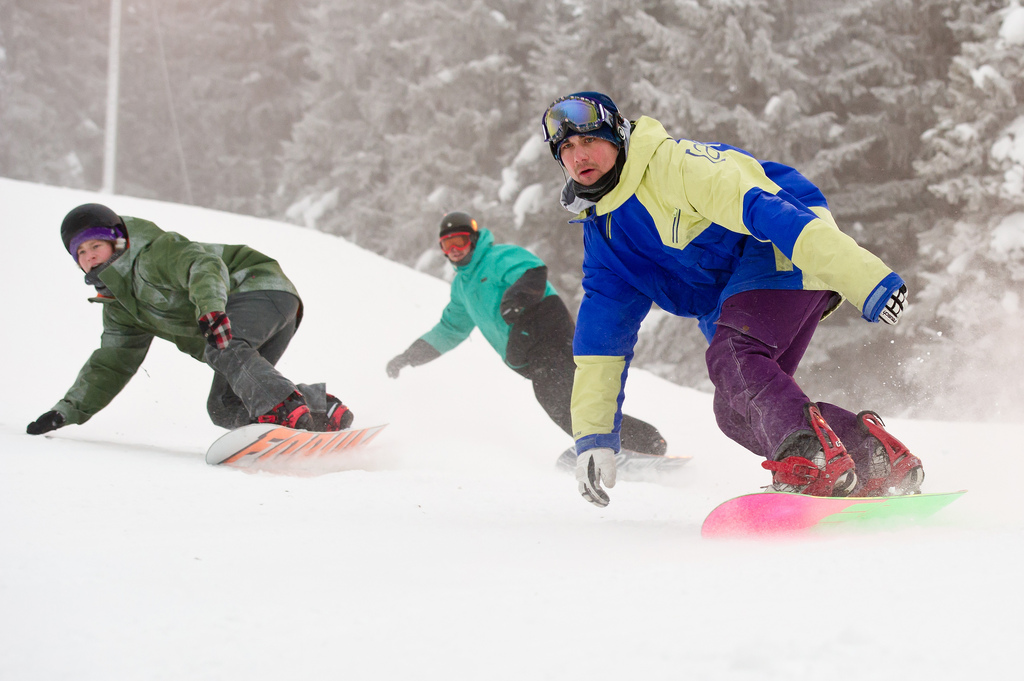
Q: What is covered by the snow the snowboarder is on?
A: The ground is covered by the snow.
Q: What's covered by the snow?
A: The ground is covered by the snow.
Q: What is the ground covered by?
A: The ground is covered by the snow.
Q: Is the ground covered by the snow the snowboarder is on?
A: Yes, the ground is covered by the snow.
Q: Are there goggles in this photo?
A: Yes, there are goggles.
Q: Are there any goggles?
A: Yes, there are goggles.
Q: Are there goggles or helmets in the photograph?
A: Yes, there are goggles.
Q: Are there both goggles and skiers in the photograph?
A: Yes, there are both goggles and a skier.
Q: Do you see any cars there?
A: No, there are no cars.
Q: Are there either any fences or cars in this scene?
A: No, there are no cars or fences.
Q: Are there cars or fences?
A: No, there are no cars or fences.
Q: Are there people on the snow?
A: Yes, there is a person on the snow.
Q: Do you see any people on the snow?
A: Yes, there is a person on the snow.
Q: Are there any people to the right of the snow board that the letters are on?
A: Yes, there is a person to the right of the snowboard.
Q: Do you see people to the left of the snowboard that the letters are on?
A: No, the person is to the right of the snow board.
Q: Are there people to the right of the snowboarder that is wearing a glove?
A: Yes, there is a person to the right of the snowboarder.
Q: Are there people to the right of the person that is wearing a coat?
A: Yes, there is a person to the right of the snowboarder.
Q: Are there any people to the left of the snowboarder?
A: No, the person is to the right of the snowboarder.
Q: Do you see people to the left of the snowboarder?
A: No, the person is to the right of the snowboarder.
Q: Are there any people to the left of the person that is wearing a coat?
A: No, the person is to the right of the snowboarder.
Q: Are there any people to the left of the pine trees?
A: Yes, there is a person to the left of the pine trees.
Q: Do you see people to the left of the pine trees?
A: Yes, there is a person to the left of the pine trees.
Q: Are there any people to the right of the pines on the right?
A: No, the person is to the left of the pines.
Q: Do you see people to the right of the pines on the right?
A: No, the person is to the left of the pines.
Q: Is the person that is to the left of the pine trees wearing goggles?
A: Yes, the person is wearing goggles.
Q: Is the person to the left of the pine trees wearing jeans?
A: No, the person is wearing goggles.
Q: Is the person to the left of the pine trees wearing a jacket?
A: Yes, the person is wearing a jacket.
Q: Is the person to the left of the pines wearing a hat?
A: No, the person is wearing a jacket.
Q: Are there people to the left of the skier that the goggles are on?
A: Yes, there is a person to the left of the skier.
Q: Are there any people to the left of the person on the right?
A: Yes, there is a person to the left of the skier.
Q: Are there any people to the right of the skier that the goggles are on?
A: No, the person is to the left of the skier.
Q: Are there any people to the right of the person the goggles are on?
A: No, the person is to the left of the skier.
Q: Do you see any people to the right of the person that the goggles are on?
A: No, the person is to the left of the skier.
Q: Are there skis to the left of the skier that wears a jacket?
A: No, there is a person to the left of the skier.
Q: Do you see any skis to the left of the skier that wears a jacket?
A: No, there is a person to the left of the skier.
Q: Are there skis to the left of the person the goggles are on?
A: No, there is a person to the left of the skier.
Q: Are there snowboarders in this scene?
A: Yes, there is a snowboarder.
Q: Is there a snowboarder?
A: Yes, there is a snowboarder.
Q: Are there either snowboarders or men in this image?
A: Yes, there is a snowboarder.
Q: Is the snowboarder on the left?
A: Yes, the snowboarder is on the left of the image.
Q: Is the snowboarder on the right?
A: No, the snowboarder is on the left of the image.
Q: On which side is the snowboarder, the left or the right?
A: The snowboarder is on the left of the image.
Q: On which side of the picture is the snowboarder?
A: The snowboarder is on the left of the image.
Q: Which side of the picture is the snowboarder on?
A: The snowboarder is on the left of the image.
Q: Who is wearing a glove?
A: The snowboarder is wearing a glove.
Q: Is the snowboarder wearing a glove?
A: Yes, the snowboarder is wearing a glove.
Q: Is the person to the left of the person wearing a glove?
A: Yes, the snowboarder is wearing a glove.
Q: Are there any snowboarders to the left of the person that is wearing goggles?
A: Yes, there is a snowboarder to the left of the person.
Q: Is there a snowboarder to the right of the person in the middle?
A: No, the snowboarder is to the left of the person.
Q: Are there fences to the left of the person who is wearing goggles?
A: No, there is a snowboarder to the left of the person.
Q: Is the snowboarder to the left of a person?
A: Yes, the snowboarder is to the left of a person.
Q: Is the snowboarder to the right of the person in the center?
A: No, the snowboarder is to the left of the person.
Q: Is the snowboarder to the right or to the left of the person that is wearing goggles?
A: The snowboarder is to the left of the person.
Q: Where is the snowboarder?
A: The snowboarder is on the snow.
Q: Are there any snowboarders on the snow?
A: Yes, there is a snowboarder on the snow.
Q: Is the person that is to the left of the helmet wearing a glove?
A: Yes, the snowboarder is wearing a glove.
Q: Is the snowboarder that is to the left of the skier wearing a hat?
A: No, the snowboarder is wearing a glove.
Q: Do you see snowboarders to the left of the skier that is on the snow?
A: Yes, there is a snowboarder to the left of the skier.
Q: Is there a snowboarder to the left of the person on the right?
A: Yes, there is a snowboarder to the left of the skier.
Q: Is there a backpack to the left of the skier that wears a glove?
A: No, there is a snowboarder to the left of the skier.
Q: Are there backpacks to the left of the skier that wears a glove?
A: No, there is a snowboarder to the left of the skier.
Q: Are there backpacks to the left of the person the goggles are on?
A: No, there is a snowboarder to the left of the skier.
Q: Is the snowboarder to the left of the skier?
A: Yes, the snowboarder is to the left of the skier.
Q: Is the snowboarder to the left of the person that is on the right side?
A: Yes, the snowboarder is to the left of the skier.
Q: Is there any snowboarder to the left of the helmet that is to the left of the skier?
A: Yes, there is a snowboarder to the left of the helmet.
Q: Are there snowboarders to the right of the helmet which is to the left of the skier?
A: No, the snowboarder is to the left of the helmet.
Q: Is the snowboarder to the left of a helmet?
A: Yes, the snowboarder is to the left of a helmet.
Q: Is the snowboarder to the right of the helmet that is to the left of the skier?
A: No, the snowboarder is to the left of the helmet.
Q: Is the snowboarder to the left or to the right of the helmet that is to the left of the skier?
A: The snowboarder is to the left of the helmet.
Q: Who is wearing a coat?
A: The snowboarder is wearing a coat.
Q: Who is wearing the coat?
A: The snowboarder is wearing a coat.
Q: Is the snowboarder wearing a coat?
A: Yes, the snowboarder is wearing a coat.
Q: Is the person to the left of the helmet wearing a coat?
A: Yes, the snowboarder is wearing a coat.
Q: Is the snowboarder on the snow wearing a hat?
A: No, the snowboarder is wearing a coat.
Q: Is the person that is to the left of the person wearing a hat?
A: No, the snowboarder is wearing a coat.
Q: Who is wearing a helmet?
A: The snowboarder is wearing a helmet.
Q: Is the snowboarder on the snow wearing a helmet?
A: Yes, the snowboarder is wearing a helmet.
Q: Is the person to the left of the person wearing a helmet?
A: Yes, the snowboarder is wearing a helmet.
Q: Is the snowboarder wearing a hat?
A: No, the snowboarder is wearing a helmet.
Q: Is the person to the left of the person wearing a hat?
A: No, the snowboarder is wearing a helmet.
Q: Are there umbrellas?
A: No, there are no umbrellas.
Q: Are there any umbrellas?
A: No, there are no umbrellas.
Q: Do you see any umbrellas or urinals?
A: No, there are no umbrellas or urinals.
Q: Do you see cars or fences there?
A: No, there are no fences or cars.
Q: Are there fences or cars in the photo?
A: No, there are no fences or cars.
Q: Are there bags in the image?
A: No, there are no bags.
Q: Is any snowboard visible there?
A: Yes, there is a snowboard.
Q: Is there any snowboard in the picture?
A: Yes, there is a snowboard.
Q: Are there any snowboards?
A: Yes, there is a snowboard.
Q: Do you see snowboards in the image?
A: Yes, there is a snowboard.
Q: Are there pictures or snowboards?
A: Yes, there is a snowboard.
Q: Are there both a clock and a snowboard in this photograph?
A: No, there is a snowboard but no clocks.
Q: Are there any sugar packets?
A: No, there are no sugar packets.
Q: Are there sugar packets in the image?
A: No, there are no sugar packets.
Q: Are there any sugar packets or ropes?
A: No, there are no sugar packets or ropes.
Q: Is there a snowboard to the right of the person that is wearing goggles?
A: Yes, there is a snowboard to the right of the person.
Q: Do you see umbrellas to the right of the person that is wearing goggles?
A: No, there is a snowboard to the right of the person.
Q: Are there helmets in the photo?
A: Yes, there is a helmet.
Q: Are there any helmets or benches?
A: Yes, there is a helmet.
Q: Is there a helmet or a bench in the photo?
A: Yes, there is a helmet.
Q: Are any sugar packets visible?
A: No, there are no sugar packets.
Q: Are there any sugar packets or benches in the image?
A: No, there are no sugar packets or benches.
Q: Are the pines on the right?
A: Yes, the pines are on the right of the image.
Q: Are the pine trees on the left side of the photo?
A: No, the pine trees are on the right of the image.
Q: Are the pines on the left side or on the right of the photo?
A: The pines are on the right of the image.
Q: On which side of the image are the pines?
A: The pines are on the right of the image.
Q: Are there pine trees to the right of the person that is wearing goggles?
A: Yes, there are pine trees to the right of the person.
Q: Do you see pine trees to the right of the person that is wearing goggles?
A: Yes, there are pine trees to the right of the person.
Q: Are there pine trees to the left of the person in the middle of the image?
A: No, the pine trees are to the right of the person.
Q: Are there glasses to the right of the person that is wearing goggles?
A: No, there are pine trees to the right of the person.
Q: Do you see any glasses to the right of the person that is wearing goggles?
A: No, there are pine trees to the right of the person.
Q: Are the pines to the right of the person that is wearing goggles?
A: Yes, the pines are to the right of the person.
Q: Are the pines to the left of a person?
A: No, the pines are to the right of a person.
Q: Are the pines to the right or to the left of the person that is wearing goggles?
A: The pines are to the right of the person.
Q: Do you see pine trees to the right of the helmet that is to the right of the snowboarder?
A: Yes, there are pine trees to the right of the helmet.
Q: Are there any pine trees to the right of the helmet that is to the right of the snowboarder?
A: Yes, there are pine trees to the right of the helmet.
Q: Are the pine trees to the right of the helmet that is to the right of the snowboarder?
A: Yes, the pine trees are to the right of the helmet.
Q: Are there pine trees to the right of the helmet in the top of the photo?
A: Yes, there are pine trees to the right of the helmet.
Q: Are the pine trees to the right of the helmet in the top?
A: Yes, the pine trees are to the right of the helmet.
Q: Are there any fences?
A: No, there are no fences.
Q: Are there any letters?
A: Yes, there are letters.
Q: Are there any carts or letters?
A: Yes, there are letters.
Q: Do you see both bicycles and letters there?
A: No, there are letters but no bikes.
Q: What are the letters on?
A: The letters are on the snowboard.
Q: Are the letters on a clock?
A: No, the letters are on the snowboard.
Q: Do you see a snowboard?
A: Yes, there is a snowboard.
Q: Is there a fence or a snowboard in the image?
A: Yes, there is a snowboard.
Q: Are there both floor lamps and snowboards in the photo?
A: No, there is a snowboard but no floor lamps.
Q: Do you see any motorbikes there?
A: No, there are no motorbikes.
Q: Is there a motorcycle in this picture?
A: No, there are no motorcycles.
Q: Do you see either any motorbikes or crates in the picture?
A: No, there are no motorbikes or crates.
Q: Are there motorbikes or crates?
A: No, there are no motorbikes or crates.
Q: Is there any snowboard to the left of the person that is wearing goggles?
A: Yes, there is a snowboard to the left of the person.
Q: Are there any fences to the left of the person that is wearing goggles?
A: No, there is a snowboard to the left of the person.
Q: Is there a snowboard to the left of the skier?
A: Yes, there is a snowboard to the left of the skier.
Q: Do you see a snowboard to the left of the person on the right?
A: Yes, there is a snowboard to the left of the skier.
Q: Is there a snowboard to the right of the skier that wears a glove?
A: No, the snowboard is to the left of the skier.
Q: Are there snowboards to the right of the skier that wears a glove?
A: No, the snowboard is to the left of the skier.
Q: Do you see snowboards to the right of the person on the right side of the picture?
A: No, the snowboard is to the left of the skier.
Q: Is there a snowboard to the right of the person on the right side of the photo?
A: No, the snowboard is to the left of the skier.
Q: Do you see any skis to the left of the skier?
A: No, there is a snowboard to the left of the skier.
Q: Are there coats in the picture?
A: Yes, there is a coat.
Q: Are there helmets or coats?
A: Yes, there is a coat.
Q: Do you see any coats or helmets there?
A: Yes, there is a coat.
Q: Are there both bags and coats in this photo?
A: No, there is a coat but no bags.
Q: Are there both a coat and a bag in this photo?
A: No, there is a coat but no bags.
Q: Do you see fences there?
A: No, there are no fences.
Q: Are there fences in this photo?
A: No, there are no fences.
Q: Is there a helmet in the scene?
A: Yes, there is a helmet.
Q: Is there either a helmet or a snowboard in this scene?
A: Yes, there is a helmet.